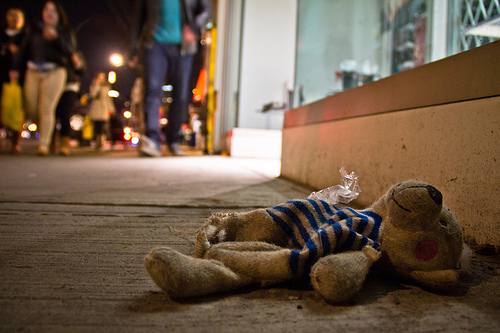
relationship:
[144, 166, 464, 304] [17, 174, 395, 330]
teddy bear on sidewalk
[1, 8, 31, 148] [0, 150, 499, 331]
person walking on sidewalk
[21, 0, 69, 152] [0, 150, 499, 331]
woman walking on sidewalk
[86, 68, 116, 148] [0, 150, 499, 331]
person walking on sidewalk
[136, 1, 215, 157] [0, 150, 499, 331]
man walking on sidewalk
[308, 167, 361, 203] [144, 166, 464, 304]
stuffing exposed on teddy bear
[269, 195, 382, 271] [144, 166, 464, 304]
stripes on teddy bear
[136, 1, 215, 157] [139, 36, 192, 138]
man wearing jeans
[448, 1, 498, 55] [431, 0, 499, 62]
gate on door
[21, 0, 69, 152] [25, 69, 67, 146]
woman wearing pants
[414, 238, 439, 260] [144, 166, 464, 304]
cheek on teddy bear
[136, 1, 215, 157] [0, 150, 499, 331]
man walking down sidewalk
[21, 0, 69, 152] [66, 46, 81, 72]
woman carrying bag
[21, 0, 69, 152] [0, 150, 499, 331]
woman walking down sidewalk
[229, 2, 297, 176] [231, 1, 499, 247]
entrance to store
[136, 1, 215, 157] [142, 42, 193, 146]
man wearing jeans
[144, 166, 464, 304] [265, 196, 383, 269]
teddy bear wearing shirt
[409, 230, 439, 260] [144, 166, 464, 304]
cheek on teddy bear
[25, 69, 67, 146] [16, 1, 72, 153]
pants on a woman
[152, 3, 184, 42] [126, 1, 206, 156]
shirt on a person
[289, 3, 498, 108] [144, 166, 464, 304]
window above teddy bear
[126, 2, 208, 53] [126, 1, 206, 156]
jacket on person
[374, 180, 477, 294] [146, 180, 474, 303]
head on teddy bear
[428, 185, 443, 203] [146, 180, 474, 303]
nose on teddy bear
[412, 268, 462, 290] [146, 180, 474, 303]
ear on teddy bear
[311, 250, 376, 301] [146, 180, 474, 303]
arm on teddy bear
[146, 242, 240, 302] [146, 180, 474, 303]
leg on teddy bear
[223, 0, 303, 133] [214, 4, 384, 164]
side of building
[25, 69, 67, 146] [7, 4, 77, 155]
pants on woman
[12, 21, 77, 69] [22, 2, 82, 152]
sweater on woman